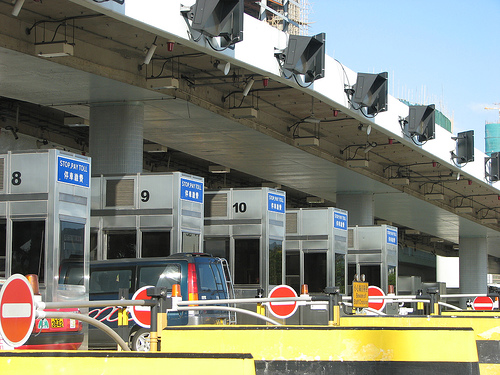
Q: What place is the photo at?
A: It is at the parking lot.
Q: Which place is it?
A: It is a parking lot.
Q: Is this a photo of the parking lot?
A: Yes, it is showing the parking lot.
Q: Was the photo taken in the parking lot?
A: Yes, it was taken in the parking lot.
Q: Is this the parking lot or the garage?
A: It is the parking lot.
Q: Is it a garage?
A: No, it is a parking lot.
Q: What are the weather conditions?
A: It is clear.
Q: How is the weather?
A: It is clear.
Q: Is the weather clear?
A: Yes, it is clear.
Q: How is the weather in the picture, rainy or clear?
A: It is clear.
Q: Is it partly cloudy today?
A: No, it is clear.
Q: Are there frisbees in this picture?
A: No, there are no frisbees.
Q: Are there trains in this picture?
A: No, there are no trains.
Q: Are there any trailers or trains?
A: No, there are no trains or trailers.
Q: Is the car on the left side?
A: Yes, the car is on the left of the image.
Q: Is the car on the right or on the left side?
A: The car is on the left of the image.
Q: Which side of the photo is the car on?
A: The car is on the left of the image.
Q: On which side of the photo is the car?
A: The car is on the left of the image.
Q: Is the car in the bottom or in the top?
A: The car is in the bottom of the image.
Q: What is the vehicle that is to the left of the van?
A: The vehicle is a car.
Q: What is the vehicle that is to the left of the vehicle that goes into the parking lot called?
A: The vehicle is a car.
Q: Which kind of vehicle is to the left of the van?
A: The vehicle is a car.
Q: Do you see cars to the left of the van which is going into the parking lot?
A: Yes, there is a car to the left of the van.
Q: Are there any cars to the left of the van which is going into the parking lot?
A: Yes, there is a car to the left of the van.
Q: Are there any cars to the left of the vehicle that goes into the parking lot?
A: Yes, there is a car to the left of the van.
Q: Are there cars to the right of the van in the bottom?
A: No, the car is to the left of the van.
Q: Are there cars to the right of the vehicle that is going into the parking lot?
A: No, the car is to the left of the van.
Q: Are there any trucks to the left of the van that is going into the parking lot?
A: No, there is a car to the left of the van.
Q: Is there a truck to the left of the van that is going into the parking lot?
A: No, there is a car to the left of the van.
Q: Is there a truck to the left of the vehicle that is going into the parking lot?
A: No, there is a car to the left of the van.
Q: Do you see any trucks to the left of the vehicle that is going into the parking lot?
A: No, there is a car to the left of the van.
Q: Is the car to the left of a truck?
A: No, the car is to the left of a van.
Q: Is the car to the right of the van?
A: No, the car is to the left of the van.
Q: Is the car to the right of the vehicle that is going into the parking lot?
A: No, the car is to the left of the van.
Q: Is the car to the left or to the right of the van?
A: The car is to the left of the van.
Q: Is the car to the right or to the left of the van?
A: The car is to the left of the van.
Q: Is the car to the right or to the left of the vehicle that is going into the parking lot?
A: The car is to the left of the van.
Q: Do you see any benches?
A: No, there are no benches.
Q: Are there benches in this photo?
A: No, there are no benches.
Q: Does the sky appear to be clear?
A: Yes, the sky is clear.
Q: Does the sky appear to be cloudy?
A: No, the sky is clear.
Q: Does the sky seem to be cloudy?
A: No, the sky is clear.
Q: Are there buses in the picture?
A: No, there are no buses.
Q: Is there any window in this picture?
A: Yes, there is a window.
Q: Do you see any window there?
A: Yes, there is a window.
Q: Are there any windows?
A: Yes, there is a window.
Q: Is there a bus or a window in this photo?
A: Yes, there is a window.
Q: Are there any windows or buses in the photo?
A: Yes, there is a window.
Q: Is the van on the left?
A: Yes, the van is on the left of the image.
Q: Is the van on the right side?
A: No, the van is on the left of the image.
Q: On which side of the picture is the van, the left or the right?
A: The van is on the left of the image.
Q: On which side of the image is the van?
A: The van is on the left of the image.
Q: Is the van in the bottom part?
A: Yes, the van is in the bottom of the image.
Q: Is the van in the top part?
A: No, the van is in the bottom of the image.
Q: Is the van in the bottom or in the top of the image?
A: The van is in the bottom of the image.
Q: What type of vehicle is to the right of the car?
A: The vehicle is a van.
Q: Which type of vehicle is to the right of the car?
A: The vehicle is a van.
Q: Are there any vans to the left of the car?
A: No, the van is to the right of the car.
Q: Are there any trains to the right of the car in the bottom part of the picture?
A: No, there is a van to the right of the car.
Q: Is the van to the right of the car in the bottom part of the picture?
A: Yes, the van is to the right of the car.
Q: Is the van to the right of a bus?
A: No, the van is to the right of the car.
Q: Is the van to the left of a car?
A: No, the van is to the right of a car.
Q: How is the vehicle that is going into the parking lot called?
A: The vehicle is a van.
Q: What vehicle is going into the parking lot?
A: The vehicle is a van.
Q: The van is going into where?
A: The van is going into the parking lot.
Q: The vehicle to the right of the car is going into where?
A: The van is going into the parking lot.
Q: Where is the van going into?
A: The van is going into the parking lot.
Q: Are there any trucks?
A: No, there are no trucks.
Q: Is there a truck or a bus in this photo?
A: No, there are no trucks or buses.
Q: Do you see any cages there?
A: No, there are no cages.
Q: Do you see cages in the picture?
A: No, there are no cages.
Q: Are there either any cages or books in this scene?
A: No, there are no cages or books.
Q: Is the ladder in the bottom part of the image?
A: Yes, the ladder is in the bottom of the image.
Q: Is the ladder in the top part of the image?
A: No, the ladder is in the bottom of the image.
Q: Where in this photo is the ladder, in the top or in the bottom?
A: The ladder is in the bottom of the image.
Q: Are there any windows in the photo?
A: Yes, there is a window.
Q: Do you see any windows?
A: Yes, there is a window.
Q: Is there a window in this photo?
A: Yes, there is a window.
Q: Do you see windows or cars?
A: Yes, there is a window.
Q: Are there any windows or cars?
A: Yes, there is a window.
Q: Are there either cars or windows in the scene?
A: Yes, there is a window.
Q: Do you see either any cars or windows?
A: Yes, there is a window.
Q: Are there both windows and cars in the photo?
A: Yes, there are both a window and a car.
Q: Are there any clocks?
A: No, there are no clocks.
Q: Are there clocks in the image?
A: No, there are no clocks.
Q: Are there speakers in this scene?
A: Yes, there is a speaker.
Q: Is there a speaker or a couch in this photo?
A: Yes, there is a speaker.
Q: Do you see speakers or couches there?
A: Yes, there is a speaker.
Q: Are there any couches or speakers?
A: Yes, there is a speaker.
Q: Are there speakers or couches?
A: Yes, there is a speaker.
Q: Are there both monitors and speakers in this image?
A: No, there is a speaker but no monitors.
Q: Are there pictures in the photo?
A: No, there are no pictures.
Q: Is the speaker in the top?
A: Yes, the speaker is in the top of the image.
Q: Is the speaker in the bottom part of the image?
A: No, the speaker is in the top of the image.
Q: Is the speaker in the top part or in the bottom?
A: The speaker is in the top of the image.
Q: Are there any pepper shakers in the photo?
A: No, there are no pepper shakers.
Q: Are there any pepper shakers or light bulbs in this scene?
A: No, there are no pepper shakers or light bulbs.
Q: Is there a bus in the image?
A: No, there are no buses.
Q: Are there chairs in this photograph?
A: No, there are no chairs.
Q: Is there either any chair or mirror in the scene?
A: No, there are no chairs or mirrors.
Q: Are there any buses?
A: No, there are no buses.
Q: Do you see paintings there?
A: No, there are no paintings.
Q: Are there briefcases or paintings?
A: No, there are no paintings or briefcases.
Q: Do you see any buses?
A: No, there are no buses.